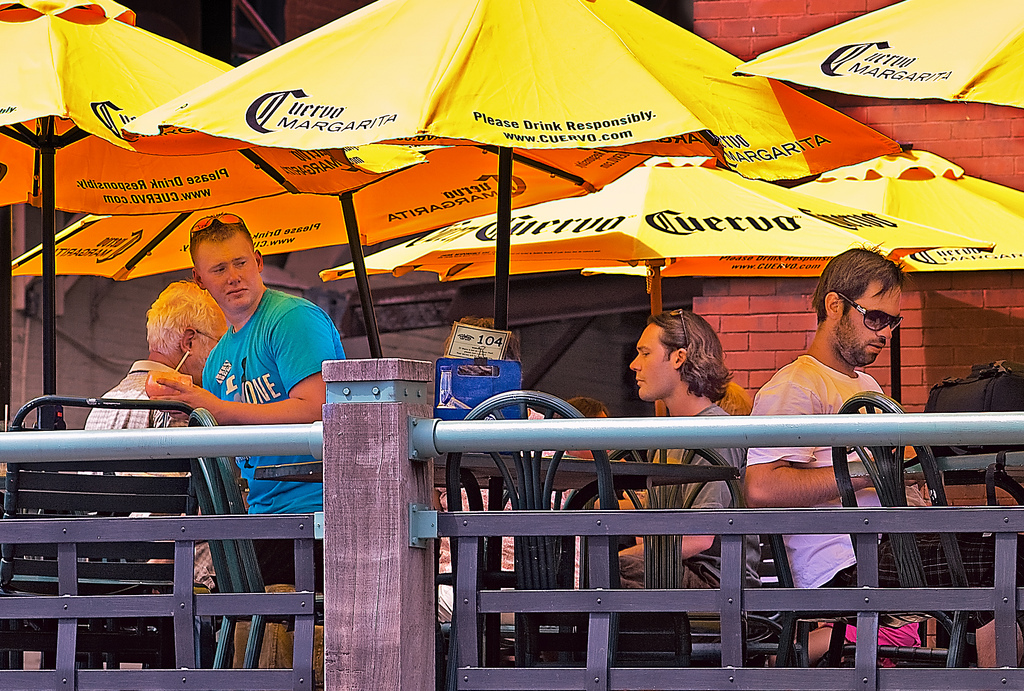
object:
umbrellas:
[121, 0, 917, 189]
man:
[79, 281, 244, 589]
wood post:
[318, 358, 433, 690]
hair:
[646, 308, 734, 402]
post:
[321, 359, 433, 625]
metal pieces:
[318, 356, 438, 423]